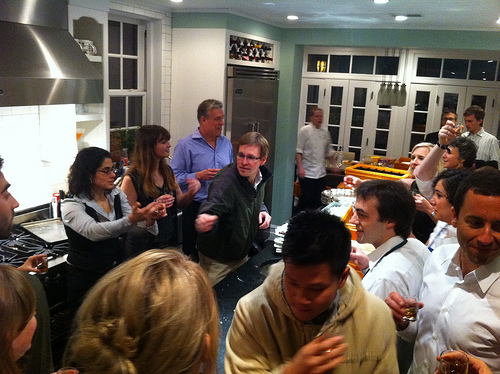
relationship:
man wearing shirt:
[415, 157, 499, 370] [411, 240, 499, 368]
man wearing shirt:
[352, 173, 428, 348] [362, 233, 433, 330]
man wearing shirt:
[458, 100, 498, 159] [461, 129, 498, 162]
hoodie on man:
[224, 259, 401, 374] [228, 206, 396, 372]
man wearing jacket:
[192, 130, 272, 278] [194, 167, 277, 267]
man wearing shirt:
[169, 91, 237, 207] [172, 126, 237, 203]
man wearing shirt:
[390, 159, 498, 372] [359, 239, 443, 300]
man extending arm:
[192, 131, 272, 287] [189, 178, 235, 229]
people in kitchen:
[1, 97, 498, 371] [0, 0, 499, 370]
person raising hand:
[418, 120, 476, 193] [442, 119, 460, 145]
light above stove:
[9, 93, 91, 154] [2, 160, 154, 280]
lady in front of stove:
[59, 146, 175, 334] [0, 203, 71, 330]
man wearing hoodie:
[228, 206, 396, 372] [224, 264, 401, 372]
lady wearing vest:
[59, 146, 175, 334] [63, 194, 126, 269]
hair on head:
[284, 212, 343, 262] [279, 209, 352, 319]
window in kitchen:
[115, 9, 157, 157] [0, 0, 499, 370]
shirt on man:
[403, 247, 497, 331] [390, 159, 498, 372]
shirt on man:
[171, 124, 265, 189] [179, 96, 266, 197]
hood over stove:
[0, 0, 110, 100] [5, 185, 83, 308]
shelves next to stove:
[72, 101, 106, 157] [0, 201, 73, 369]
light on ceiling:
[286, 13, 298, 24] [116, 0, 499, 30]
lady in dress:
[59, 143, 175, 311] [62, 183, 139, 318]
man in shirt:
[347, 178, 430, 374] [361, 234, 433, 330]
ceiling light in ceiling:
[394, 16, 408, 22] [112, 0, 477, 25]